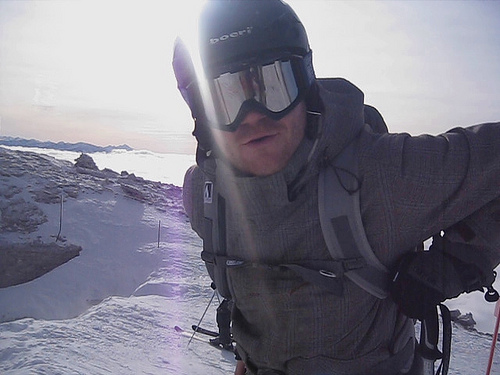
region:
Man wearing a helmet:
[165, 0, 322, 122]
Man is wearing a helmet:
[167, 0, 320, 141]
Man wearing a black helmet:
[165, 0, 321, 132]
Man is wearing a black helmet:
[170, 0, 317, 149]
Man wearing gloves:
[391, 245, 468, 327]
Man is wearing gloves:
[383, 250, 463, 320]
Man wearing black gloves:
[384, 247, 461, 320]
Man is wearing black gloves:
[384, 249, 466, 321]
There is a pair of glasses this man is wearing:
[226, 65, 266, 143]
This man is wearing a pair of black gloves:
[396, 269, 424, 314]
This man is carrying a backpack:
[320, 215, 365, 284]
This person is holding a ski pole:
[188, 308, 205, 357]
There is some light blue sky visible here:
[407, 57, 417, 84]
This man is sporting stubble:
[247, 146, 277, 216]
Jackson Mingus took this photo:
[81, 98, 163, 335]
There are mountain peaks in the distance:
[39, 125, 54, 151]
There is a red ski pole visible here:
[230, 360, 236, 370]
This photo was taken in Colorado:
[117, 102, 159, 292]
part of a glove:
[397, 294, 401, 316]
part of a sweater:
[303, 275, 314, 300]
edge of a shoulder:
[314, 301, 324, 329]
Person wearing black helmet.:
[195, 20, 278, 46]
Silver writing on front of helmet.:
[204, 32, 261, 54]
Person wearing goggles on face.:
[181, 61, 305, 105]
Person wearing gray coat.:
[261, 294, 323, 349]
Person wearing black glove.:
[398, 262, 443, 325]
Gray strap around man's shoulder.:
[331, 219, 365, 284]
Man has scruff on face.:
[225, 155, 264, 162]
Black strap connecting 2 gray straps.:
[225, 244, 326, 296]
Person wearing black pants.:
[214, 313, 227, 333]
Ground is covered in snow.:
[88, 316, 149, 363]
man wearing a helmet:
[162, 12, 333, 166]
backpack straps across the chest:
[198, 171, 387, 299]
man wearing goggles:
[162, 60, 330, 170]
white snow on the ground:
[73, 194, 173, 373]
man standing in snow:
[110, 23, 465, 374]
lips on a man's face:
[241, 129, 281, 154]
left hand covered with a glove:
[383, 236, 489, 328]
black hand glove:
[389, 231, 472, 321]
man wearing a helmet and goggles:
[154, 12, 340, 173]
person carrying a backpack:
[161, 0, 498, 333]